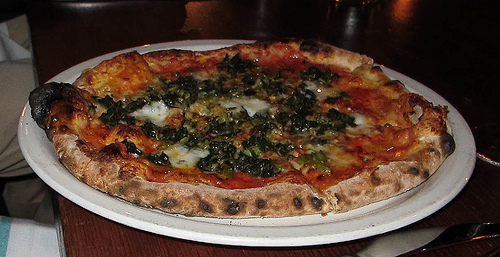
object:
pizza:
[25, 38, 460, 223]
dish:
[14, 34, 482, 253]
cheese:
[217, 91, 270, 119]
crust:
[24, 74, 93, 144]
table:
[17, 0, 498, 257]